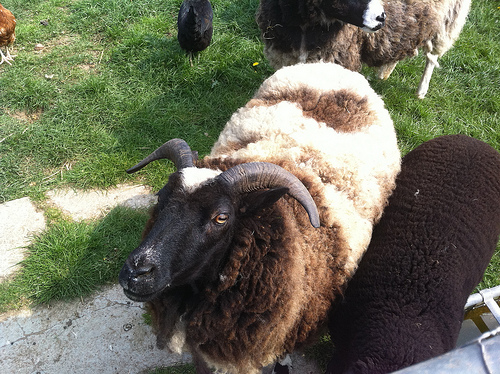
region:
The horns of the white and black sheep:
[121, 134, 324, 231]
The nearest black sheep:
[321, 130, 498, 372]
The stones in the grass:
[0, 177, 169, 283]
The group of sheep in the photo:
[120, 0, 497, 372]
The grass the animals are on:
[0, 1, 497, 306]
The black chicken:
[171, 1, 221, 68]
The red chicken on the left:
[0, 3, 25, 71]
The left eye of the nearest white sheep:
[210, 203, 232, 230]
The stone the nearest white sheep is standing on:
[0, 276, 206, 373]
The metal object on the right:
[374, 279, 499, 372]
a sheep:
[266, 265, 339, 339]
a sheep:
[264, 274, 291, 348]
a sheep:
[251, 284, 299, 365]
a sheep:
[228, 221, 303, 356]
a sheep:
[259, 214, 326, 362]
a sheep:
[259, 267, 292, 312]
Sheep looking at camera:
[107, 104, 302, 369]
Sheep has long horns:
[130, 127, 355, 243]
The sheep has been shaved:
[406, 145, 483, 338]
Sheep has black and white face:
[118, 95, 275, 370]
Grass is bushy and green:
[47, 70, 154, 174]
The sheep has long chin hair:
[147, 297, 207, 362]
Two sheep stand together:
[135, 55, 468, 368]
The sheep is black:
[385, 103, 499, 358]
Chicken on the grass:
[0, 7, 44, 109]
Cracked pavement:
[5, 299, 199, 365]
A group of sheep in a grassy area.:
[0, 0, 497, 370]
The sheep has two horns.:
[110, 120, 325, 315]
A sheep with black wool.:
[330, 126, 495, 366]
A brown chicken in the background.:
[0, 5, 30, 61]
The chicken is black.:
[152, 0, 233, 71]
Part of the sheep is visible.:
[256, 0, 481, 75]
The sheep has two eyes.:
[145, 185, 233, 230]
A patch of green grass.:
[48, 233, 108, 271]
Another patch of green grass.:
[75, 80, 212, 113]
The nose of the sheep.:
[374, 7, 390, 27]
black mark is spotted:
[120, 322, 137, 347]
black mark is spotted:
[122, 311, 133, 332]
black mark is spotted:
[125, 322, 132, 339]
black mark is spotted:
[119, 323, 136, 331]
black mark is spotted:
[125, 323, 136, 329]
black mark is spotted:
[124, 325, 135, 334]